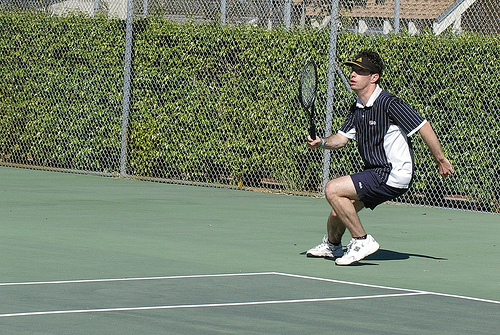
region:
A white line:
[159, 216, 261, 328]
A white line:
[151, 174, 313, 327]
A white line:
[119, 136, 264, 333]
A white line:
[81, 156, 204, 319]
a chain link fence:
[0, 0, 499, 202]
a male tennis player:
[293, 42, 456, 268]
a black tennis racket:
[293, 55, 320, 146]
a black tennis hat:
[341, 47, 386, 74]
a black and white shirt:
[335, 84, 425, 189]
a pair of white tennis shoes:
[305, 237, 383, 268]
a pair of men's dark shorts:
[346, 165, 395, 212]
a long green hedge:
[0, 5, 497, 207]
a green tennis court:
[0, 174, 497, 333]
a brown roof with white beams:
[297, 0, 472, 38]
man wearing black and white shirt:
[350, 105, 416, 165]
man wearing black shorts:
[350, 170, 380, 196]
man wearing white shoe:
[342, 238, 377, 259]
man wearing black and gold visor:
[349, 47, 381, 74]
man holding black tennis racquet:
[287, 52, 327, 134]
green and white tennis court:
[10, 250, 276, 333]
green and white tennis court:
[263, 268, 480, 323]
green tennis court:
[17, 179, 180, 261]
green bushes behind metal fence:
[14, 4, 119, 144]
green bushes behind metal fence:
[142, 6, 282, 150]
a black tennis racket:
[277, 55, 335, 151]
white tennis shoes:
[288, 227, 388, 273]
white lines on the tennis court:
[1, 244, 307, 334]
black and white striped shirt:
[315, 92, 437, 201]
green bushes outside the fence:
[2, 9, 324, 200]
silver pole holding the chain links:
[117, 0, 137, 182]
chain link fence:
[147, 7, 263, 169]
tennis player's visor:
[340, 38, 391, 78]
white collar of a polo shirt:
[343, 73, 392, 118]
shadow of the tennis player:
[336, 238, 450, 290]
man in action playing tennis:
[35, 17, 471, 304]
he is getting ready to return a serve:
[268, 36, 467, 272]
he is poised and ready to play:
[246, 52, 421, 280]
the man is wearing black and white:
[278, 33, 457, 292]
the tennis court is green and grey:
[7, 163, 479, 330]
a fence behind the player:
[8, 6, 488, 213]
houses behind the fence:
[28, 2, 499, 55]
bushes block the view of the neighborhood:
[2, 6, 492, 213]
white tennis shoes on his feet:
[256, 236, 430, 313]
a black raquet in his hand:
[271, 53, 341, 160]